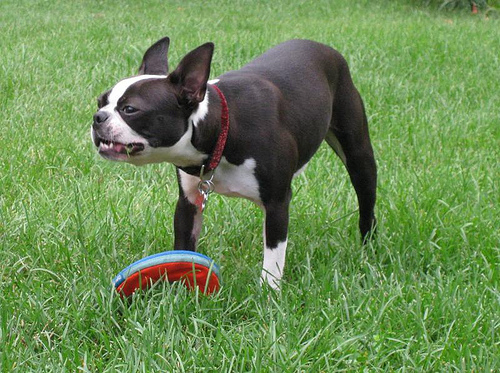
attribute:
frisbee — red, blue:
[104, 247, 229, 314]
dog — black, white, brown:
[84, 32, 409, 303]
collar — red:
[188, 80, 235, 220]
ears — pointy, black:
[135, 34, 219, 108]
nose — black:
[86, 110, 112, 132]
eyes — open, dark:
[95, 96, 141, 118]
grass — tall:
[1, 1, 500, 372]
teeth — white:
[95, 136, 120, 152]